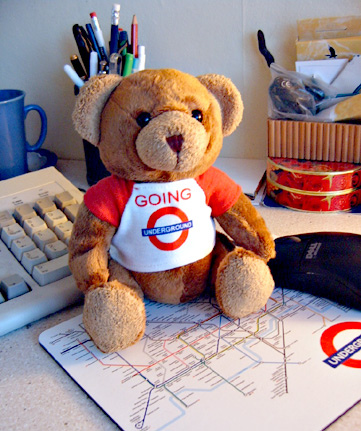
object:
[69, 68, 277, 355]
bear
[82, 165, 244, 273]
shirt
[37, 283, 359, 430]
mouse pad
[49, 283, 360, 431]
map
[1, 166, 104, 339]
keyboard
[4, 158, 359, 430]
desk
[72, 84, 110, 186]
cup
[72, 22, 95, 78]
pens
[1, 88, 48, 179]
cup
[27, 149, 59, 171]
plate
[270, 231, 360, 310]
mouse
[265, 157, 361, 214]
can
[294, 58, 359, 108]
paper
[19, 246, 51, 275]
numbers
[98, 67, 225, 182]
face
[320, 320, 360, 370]
logo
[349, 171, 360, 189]
roses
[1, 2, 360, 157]
wall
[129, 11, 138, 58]
pencils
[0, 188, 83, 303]
keys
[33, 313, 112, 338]
edge